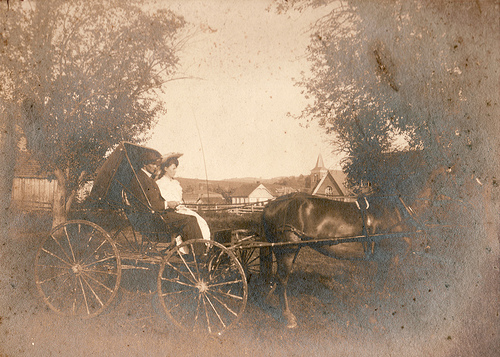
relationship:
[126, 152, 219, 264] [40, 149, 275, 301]
man driving buggy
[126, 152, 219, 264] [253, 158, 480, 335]
man in a horse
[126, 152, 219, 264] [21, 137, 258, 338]
man in a buggy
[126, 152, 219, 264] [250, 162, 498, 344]
man riding in horse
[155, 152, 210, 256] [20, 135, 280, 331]
woman riding in buggy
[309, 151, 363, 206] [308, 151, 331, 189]
churck with steeple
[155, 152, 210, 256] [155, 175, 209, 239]
woman in dress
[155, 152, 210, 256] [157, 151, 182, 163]
woman with hat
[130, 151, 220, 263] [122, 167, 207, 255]
man in suit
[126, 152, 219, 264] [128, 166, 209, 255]
man in suit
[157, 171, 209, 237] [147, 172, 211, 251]
woman in dress